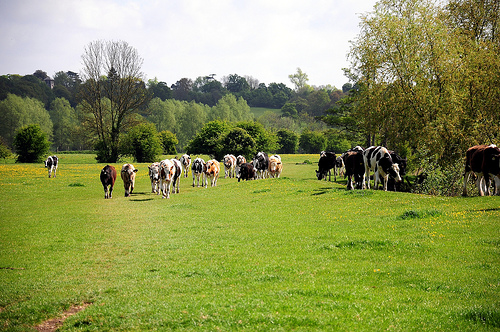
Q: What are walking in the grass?
A: Cattle.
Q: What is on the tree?
A: No leaves.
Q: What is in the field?
A: Bunch of cows.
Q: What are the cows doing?
A: They are eating.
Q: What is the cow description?
A: Black and white.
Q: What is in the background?
A: Pine trees.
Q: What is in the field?
A: Trees.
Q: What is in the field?
A: Cattle.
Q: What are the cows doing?
A: Walking.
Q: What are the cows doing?
A: Walking.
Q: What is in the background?
A: Tree without leaves.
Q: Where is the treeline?
A: Behind the field.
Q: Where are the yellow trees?
A: Right of field.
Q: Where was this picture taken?
A: A grassy pasture.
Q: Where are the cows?
A: In the pasture.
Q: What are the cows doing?
A: Walking in a field.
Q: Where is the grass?
A: On the ground.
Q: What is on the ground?
A: Grass.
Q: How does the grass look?
A: Short and green.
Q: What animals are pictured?
A: Cows.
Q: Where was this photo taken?
A: Looks like a pasture.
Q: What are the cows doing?
A: They are walking.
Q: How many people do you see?
A: None.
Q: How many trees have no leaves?
A: Just one.